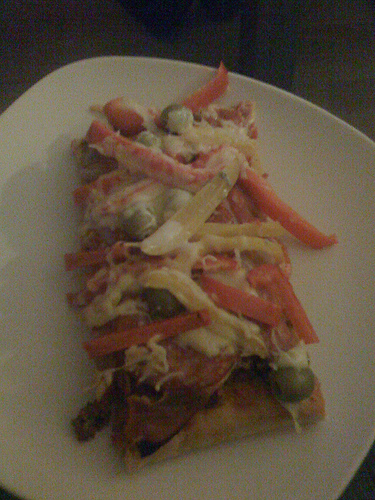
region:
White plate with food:
[68, 91, 360, 493]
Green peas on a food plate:
[134, 281, 316, 403]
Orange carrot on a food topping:
[77, 308, 210, 362]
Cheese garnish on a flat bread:
[97, 264, 305, 375]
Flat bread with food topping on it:
[113, 380, 337, 481]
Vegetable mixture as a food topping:
[80, 169, 284, 326]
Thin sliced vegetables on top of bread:
[81, 125, 270, 258]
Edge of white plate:
[343, 436, 372, 486]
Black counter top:
[2, 5, 352, 57]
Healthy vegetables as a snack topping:
[92, 208, 277, 354]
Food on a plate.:
[17, 60, 342, 460]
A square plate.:
[0, 60, 352, 484]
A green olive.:
[245, 331, 326, 415]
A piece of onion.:
[120, 137, 255, 258]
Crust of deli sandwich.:
[96, 353, 336, 455]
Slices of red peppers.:
[190, 241, 316, 339]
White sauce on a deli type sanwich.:
[71, 99, 281, 279]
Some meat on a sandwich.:
[99, 351, 234, 450]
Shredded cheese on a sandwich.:
[98, 284, 220, 396]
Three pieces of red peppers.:
[85, 262, 338, 362]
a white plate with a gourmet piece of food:
[1, 48, 367, 491]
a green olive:
[267, 360, 312, 400]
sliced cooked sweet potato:
[233, 158, 338, 251]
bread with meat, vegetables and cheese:
[70, 105, 304, 429]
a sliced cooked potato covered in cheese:
[139, 165, 234, 246]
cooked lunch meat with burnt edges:
[79, 345, 242, 444]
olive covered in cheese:
[154, 106, 195, 132]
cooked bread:
[202, 387, 276, 441]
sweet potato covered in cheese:
[92, 123, 211, 193]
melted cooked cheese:
[141, 221, 186, 254]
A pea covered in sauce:
[158, 90, 193, 140]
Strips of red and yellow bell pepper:
[154, 175, 352, 271]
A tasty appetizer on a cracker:
[140, 383, 339, 466]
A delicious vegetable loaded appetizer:
[69, 47, 334, 499]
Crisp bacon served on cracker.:
[112, 363, 272, 456]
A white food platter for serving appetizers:
[256, 2, 374, 194]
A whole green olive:
[275, 370, 328, 406]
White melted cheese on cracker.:
[267, 328, 320, 371]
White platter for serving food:
[13, 309, 55, 444]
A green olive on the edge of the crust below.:
[270, 370, 311, 411]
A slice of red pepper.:
[254, 268, 320, 348]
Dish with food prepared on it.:
[21, 93, 372, 421]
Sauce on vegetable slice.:
[89, 117, 203, 195]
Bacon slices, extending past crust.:
[75, 357, 228, 452]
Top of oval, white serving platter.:
[4, 77, 370, 168]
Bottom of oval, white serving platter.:
[0, 420, 370, 495]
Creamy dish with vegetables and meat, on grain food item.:
[82, 111, 324, 434]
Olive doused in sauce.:
[163, 105, 194, 135]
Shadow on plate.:
[0, 132, 115, 462]